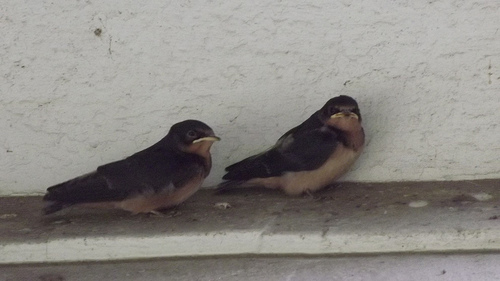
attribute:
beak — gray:
[185, 125, 222, 145]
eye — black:
[183, 127, 196, 139]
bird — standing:
[218, 94, 368, 209]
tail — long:
[42, 164, 107, 216]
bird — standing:
[217, 92, 366, 196]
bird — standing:
[128, 98, 453, 210]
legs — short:
[148, 206, 168, 222]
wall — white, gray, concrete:
[48, 9, 480, 130]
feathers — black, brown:
[280, 132, 296, 150]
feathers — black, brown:
[215, 164, 245, 193]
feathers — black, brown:
[338, 95, 357, 104]